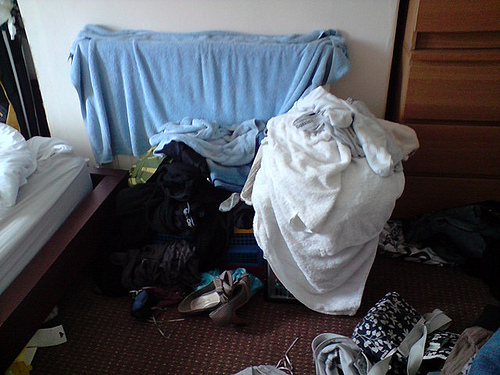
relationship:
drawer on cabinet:
[403, 50, 498, 125] [402, 1, 498, 212]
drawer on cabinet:
[399, 122, 499, 179] [402, 1, 498, 212]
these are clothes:
[109, 154, 238, 354] [47, 33, 407, 359]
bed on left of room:
[0, 120, 132, 372] [39, 55, 189, 319]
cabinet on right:
[402, 1, 498, 212] [345, 74, 439, 149]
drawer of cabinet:
[405, 6, 499, 57] [384, 1, 499, 213]